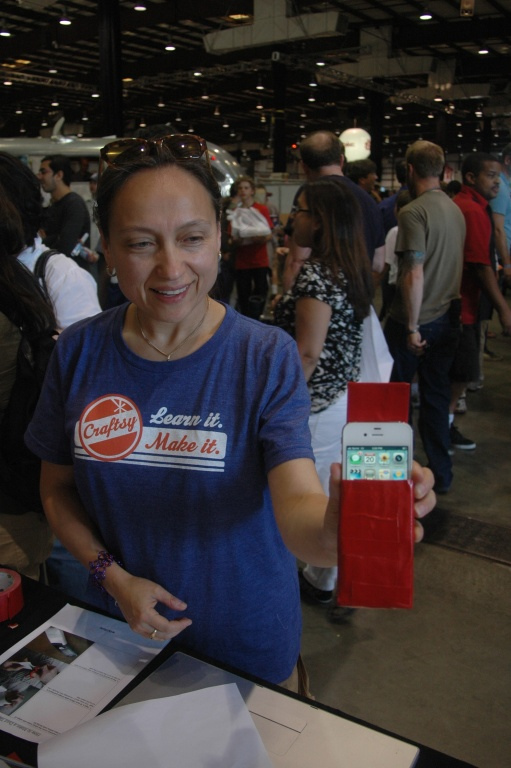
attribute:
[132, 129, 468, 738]
show — lit, crowded, female, male, adult, dark, exhibit